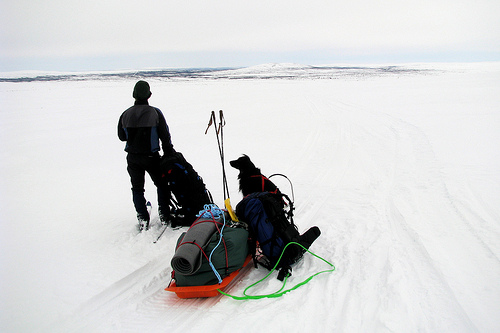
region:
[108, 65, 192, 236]
a skier on a snow field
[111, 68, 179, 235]
skier wears black cloths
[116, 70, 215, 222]
skier holds a black bag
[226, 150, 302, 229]
a dog near a man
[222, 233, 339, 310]
a string color green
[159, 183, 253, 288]
a backpack with a mat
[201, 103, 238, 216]
two black snow poles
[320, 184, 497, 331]
marks of skis on the snow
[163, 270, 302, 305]
a red sledge with green string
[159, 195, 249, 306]
a backpack over a sledge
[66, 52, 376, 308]
man is standing in the snow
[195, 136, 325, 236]
dog is sitting in the snow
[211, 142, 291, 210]
the dog is black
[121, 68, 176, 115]
man is wearing a hat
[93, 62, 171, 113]
the hat is black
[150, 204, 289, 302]
bags are on a sled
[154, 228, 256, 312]
the sled is orange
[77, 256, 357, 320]
lines in the snow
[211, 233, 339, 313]
the string is green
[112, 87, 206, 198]
man is holding a bag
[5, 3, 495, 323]
Photo taken during the day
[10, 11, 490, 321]
Photo taken in the winter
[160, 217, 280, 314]
Orange sled to carry the gear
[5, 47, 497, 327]
The ground is white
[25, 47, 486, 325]
Ground is covered in snow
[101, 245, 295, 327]
Tracks in the snow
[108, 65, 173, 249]
Man on skis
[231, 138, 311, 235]
Black dog with red harness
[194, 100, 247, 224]
Ski poles stuck in snow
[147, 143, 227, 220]
Backpack in the snow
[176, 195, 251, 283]
Bags on a sled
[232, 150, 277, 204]
dog pulling a sle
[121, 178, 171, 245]
Man on skis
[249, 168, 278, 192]
Dog with a red strap on its back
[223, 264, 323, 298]
Green string on sled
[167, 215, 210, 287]
Sleeping bag on sled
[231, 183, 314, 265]
Backpack on the ground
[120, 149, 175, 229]
Man wearing black pants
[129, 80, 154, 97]
Man wearing a hat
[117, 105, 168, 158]
Man wearing a gray jacket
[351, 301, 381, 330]
Snow on the ground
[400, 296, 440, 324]
Snow on the ground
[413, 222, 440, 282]
Snow on the ground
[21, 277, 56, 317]
Snow on the ground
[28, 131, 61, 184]
Snow on the ground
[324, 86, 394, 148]
Snow on the ground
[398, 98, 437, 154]
Snow on the ground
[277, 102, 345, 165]
Snow on the ground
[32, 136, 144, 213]
Snow on the ground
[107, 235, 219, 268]
Snow on the ground